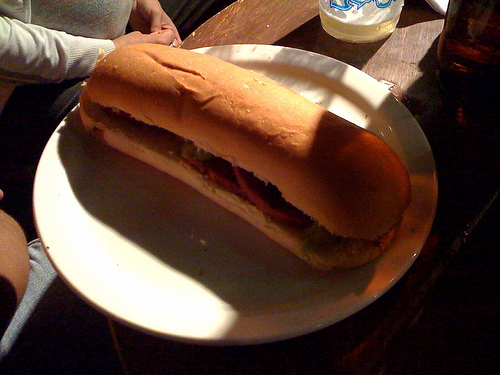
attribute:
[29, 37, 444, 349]
plate — white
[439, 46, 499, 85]
bottom — brown